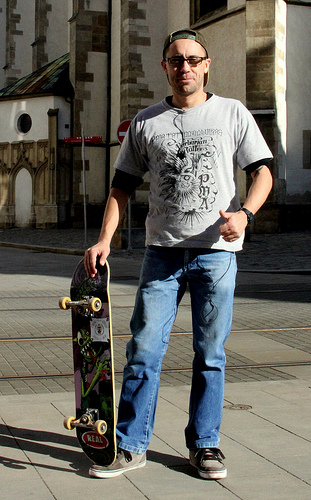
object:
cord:
[195, 250, 231, 327]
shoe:
[188, 444, 229, 482]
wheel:
[58, 295, 71, 311]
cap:
[161, 25, 210, 86]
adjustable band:
[169, 32, 196, 44]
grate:
[225, 399, 254, 415]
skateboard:
[58, 253, 116, 467]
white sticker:
[88, 316, 108, 344]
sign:
[116, 118, 131, 147]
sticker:
[80, 430, 109, 452]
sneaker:
[85, 443, 146, 478]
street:
[2, 249, 310, 498]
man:
[83, 27, 273, 480]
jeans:
[116, 241, 236, 455]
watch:
[239, 204, 255, 232]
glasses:
[163, 55, 208, 70]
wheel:
[85, 295, 101, 313]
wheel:
[63, 412, 74, 434]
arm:
[217, 99, 274, 243]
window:
[15, 112, 30, 134]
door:
[10, 162, 34, 230]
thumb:
[217, 207, 235, 221]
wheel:
[91, 418, 104, 435]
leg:
[185, 270, 234, 480]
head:
[160, 28, 212, 98]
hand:
[216, 206, 248, 243]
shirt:
[115, 95, 273, 251]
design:
[157, 132, 219, 227]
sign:
[63, 133, 103, 144]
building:
[2, 3, 310, 229]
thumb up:
[216, 211, 240, 243]